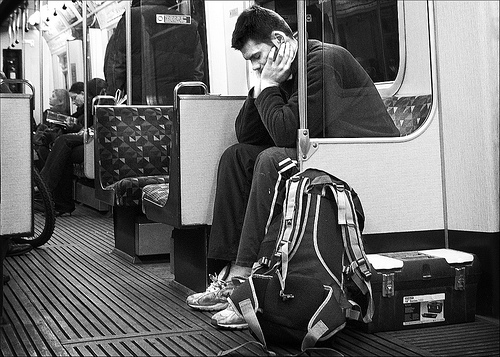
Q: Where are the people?
A: On the subway.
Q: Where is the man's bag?
A: On the floor.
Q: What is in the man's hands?
A: His head.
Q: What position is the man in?
A: Seated.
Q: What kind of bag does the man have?
A: Backpack.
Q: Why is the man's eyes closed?
A: He is tired.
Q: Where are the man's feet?
A: On the floor.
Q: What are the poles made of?
A: Metal.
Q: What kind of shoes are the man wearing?
A: Sneakers.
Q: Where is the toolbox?
A: On the floor.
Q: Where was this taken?
A: Subway car.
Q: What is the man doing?
A: Sitting.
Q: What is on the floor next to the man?
A: Backpack and case.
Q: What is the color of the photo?
A: Black and white.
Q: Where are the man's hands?
A: His face.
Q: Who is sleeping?
A: Man sitting down.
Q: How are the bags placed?
A: On the floor.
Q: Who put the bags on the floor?
A: The man.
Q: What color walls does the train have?
A: White.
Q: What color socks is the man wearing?
A: White.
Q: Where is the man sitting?
A: On a seat.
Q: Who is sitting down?
A: The man.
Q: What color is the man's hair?
A: Black.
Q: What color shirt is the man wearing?
A: Black.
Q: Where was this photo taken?
A: A train.